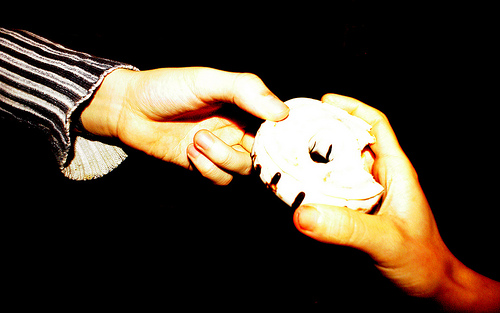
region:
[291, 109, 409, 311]
a hand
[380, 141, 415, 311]
a hand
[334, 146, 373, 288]
a hand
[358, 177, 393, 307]
a hand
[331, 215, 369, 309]
a hand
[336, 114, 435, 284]
a hand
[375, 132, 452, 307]
a hand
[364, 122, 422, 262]
a hand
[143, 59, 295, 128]
the thumb of a person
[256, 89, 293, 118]
the thumb nail of a person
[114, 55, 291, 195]
the hand of a person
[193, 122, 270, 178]
the finger of a person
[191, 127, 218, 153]
the finger nail of a person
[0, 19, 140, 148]
the arm of a person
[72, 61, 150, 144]
the wrist of a person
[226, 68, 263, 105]
the thumb knuckle of a person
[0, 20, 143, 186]
a black and white sleeve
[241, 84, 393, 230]
a donut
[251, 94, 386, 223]
a white donut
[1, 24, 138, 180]
a long black and silver sleeve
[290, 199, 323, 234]
a dirty thumbnail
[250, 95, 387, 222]
a white donut with chocolate drizzle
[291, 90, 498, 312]
a right hand grasping a donut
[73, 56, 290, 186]
a left hand grasping a donut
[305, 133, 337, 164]
the hole in the middle of the donut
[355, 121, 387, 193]
a bite taken out of the donut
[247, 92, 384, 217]
a donut with a bite taken out of it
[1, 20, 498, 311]
two hands holding a donut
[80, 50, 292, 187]
Hand holding donut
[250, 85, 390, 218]
Donut has part bit off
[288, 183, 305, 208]
Chocolate icing on donut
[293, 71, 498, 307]
Hand holding donut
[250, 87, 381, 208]
Donut is small and white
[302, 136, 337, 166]
Hole in middle of donut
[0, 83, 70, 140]
Black stripe on sleeve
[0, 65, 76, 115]
Black stripe on sleeve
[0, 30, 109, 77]
Black stripe on sleeve